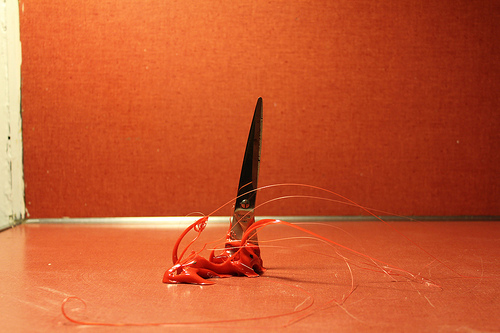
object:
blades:
[235, 96, 266, 208]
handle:
[222, 205, 269, 275]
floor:
[1, 218, 500, 331]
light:
[27, 216, 231, 223]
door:
[21, 4, 499, 218]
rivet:
[241, 199, 251, 208]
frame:
[3, 1, 26, 231]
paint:
[3, 3, 23, 230]